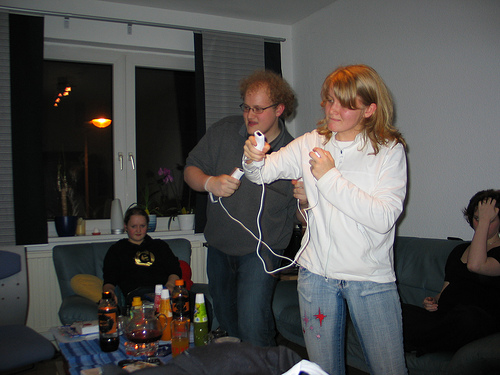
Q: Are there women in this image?
A: Yes, there is a woman.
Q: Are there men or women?
A: Yes, there is a woman.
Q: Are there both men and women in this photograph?
A: Yes, there are both a woman and a man.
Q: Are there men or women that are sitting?
A: Yes, the woman is sitting.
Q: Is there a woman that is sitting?
A: Yes, there is a woman that is sitting.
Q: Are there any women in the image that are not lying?
A: Yes, there is a woman that is sitting.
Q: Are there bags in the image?
A: No, there are no bags.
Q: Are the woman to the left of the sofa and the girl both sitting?
A: Yes, both the woman and the girl are sitting.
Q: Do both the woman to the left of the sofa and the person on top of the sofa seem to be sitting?
A: Yes, both the woman and the girl are sitting.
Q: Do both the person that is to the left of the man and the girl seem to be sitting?
A: Yes, both the woman and the girl are sitting.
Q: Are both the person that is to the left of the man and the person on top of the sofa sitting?
A: Yes, both the woman and the girl are sitting.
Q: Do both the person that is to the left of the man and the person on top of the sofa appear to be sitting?
A: Yes, both the woman and the girl are sitting.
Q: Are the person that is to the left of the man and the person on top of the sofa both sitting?
A: Yes, both the woman and the girl are sitting.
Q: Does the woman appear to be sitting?
A: Yes, the woman is sitting.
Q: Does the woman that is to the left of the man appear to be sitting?
A: Yes, the woman is sitting.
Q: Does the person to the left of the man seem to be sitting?
A: Yes, the woman is sitting.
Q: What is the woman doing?
A: The woman is sitting.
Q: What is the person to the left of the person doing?
A: The woman is sitting.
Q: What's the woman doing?
A: The woman is sitting.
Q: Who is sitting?
A: The woman is sitting.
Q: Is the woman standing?
A: No, the woman is sitting.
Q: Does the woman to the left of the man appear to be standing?
A: No, the woman is sitting.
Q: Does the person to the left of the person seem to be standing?
A: No, the woman is sitting.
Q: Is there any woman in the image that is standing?
A: No, there is a woman but she is sitting.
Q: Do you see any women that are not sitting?
A: No, there is a woman but she is sitting.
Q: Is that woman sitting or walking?
A: The woman is sitting.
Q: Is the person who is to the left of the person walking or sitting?
A: The woman is sitting.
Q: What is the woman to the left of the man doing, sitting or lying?
A: The woman is sitting.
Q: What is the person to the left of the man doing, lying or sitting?
A: The woman is sitting.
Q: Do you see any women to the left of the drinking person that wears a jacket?
A: Yes, there is a woman to the left of the person.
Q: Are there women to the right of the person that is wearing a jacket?
A: No, the woman is to the left of the person.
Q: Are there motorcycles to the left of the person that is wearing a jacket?
A: No, there is a woman to the left of the person.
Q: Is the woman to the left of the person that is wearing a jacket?
A: Yes, the woman is to the left of the person.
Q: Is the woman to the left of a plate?
A: No, the woman is to the left of the person.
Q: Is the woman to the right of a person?
A: No, the woman is to the left of a person.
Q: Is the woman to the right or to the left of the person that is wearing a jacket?
A: The woman is to the left of the person.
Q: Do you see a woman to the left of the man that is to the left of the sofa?
A: Yes, there is a woman to the left of the man.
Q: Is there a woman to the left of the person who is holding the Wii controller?
A: Yes, there is a woman to the left of the man.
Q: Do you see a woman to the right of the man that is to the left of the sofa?
A: No, the woman is to the left of the man.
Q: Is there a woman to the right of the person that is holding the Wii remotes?
A: No, the woman is to the left of the man.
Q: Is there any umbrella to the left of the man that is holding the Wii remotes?
A: No, there is a woman to the left of the man.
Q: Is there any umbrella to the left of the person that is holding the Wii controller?
A: No, there is a woman to the left of the man.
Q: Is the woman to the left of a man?
A: Yes, the woman is to the left of a man.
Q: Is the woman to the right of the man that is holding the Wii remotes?
A: No, the woman is to the left of the man.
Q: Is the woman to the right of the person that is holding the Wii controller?
A: No, the woman is to the left of the man.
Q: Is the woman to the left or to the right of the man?
A: The woman is to the left of the man.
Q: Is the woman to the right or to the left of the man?
A: The woman is to the left of the man.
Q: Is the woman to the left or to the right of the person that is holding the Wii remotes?
A: The woman is to the left of the man.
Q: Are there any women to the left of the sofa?
A: Yes, there is a woman to the left of the sofa.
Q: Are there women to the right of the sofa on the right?
A: No, the woman is to the left of the sofa.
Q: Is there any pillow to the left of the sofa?
A: No, there is a woman to the left of the sofa.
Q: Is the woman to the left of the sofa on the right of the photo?
A: Yes, the woman is to the left of the sofa.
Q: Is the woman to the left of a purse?
A: No, the woman is to the left of the sofa.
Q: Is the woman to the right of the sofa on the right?
A: No, the woman is to the left of the sofa.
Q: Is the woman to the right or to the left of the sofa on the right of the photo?
A: The woman is to the left of the sofa.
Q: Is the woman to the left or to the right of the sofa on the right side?
A: The woman is to the left of the sofa.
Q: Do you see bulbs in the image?
A: No, there are no bulbs.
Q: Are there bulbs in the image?
A: No, there are no bulbs.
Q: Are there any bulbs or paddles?
A: No, there are no bulbs or paddles.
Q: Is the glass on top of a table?
A: Yes, the glass is on top of a table.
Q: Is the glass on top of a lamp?
A: No, the glass is on top of a table.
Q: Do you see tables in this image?
A: Yes, there is a table.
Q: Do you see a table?
A: Yes, there is a table.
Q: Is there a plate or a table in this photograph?
A: Yes, there is a table.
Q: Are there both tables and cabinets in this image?
A: No, there is a table but no cabinets.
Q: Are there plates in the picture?
A: No, there are no plates.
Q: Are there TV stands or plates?
A: No, there are no plates or TV stands.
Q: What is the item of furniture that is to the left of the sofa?
A: The piece of furniture is a table.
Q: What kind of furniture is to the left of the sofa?
A: The piece of furniture is a table.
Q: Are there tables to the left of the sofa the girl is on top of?
A: Yes, there is a table to the left of the sofa.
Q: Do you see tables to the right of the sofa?
A: No, the table is to the left of the sofa.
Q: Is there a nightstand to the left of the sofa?
A: No, there is a table to the left of the sofa.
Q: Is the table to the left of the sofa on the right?
A: Yes, the table is to the left of the sofa.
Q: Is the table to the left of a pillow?
A: No, the table is to the left of the sofa.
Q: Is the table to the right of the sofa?
A: No, the table is to the left of the sofa.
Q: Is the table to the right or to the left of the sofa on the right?
A: The table is to the left of the sofa.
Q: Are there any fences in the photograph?
A: No, there are no fences.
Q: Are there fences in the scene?
A: No, there are no fences.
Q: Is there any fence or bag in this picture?
A: No, there are no fences or bags.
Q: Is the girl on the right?
A: Yes, the girl is on the right of the image.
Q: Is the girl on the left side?
A: No, the girl is on the right of the image.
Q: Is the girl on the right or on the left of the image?
A: The girl is on the right of the image.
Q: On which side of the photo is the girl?
A: The girl is on the right of the image.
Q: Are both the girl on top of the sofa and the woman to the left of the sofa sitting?
A: Yes, both the girl and the woman are sitting.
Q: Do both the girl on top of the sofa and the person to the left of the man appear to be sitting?
A: Yes, both the girl and the woman are sitting.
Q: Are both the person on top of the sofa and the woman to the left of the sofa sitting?
A: Yes, both the girl and the woman are sitting.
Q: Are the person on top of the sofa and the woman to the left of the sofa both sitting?
A: Yes, both the girl and the woman are sitting.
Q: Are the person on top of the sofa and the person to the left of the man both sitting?
A: Yes, both the girl and the woman are sitting.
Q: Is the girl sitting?
A: Yes, the girl is sitting.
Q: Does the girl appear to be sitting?
A: Yes, the girl is sitting.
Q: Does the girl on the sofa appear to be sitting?
A: Yes, the girl is sitting.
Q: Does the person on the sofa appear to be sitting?
A: Yes, the girl is sitting.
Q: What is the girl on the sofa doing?
A: The girl is sitting.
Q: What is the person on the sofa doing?
A: The girl is sitting.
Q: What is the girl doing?
A: The girl is sitting.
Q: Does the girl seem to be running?
A: No, the girl is sitting.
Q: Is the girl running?
A: No, the girl is sitting.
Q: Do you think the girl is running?
A: No, the girl is sitting.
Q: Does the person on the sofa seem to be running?
A: No, the girl is sitting.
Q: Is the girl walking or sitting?
A: The girl is sitting.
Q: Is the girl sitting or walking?
A: The girl is sitting.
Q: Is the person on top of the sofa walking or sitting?
A: The girl is sitting.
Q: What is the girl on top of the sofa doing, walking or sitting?
A: The girl is sitting.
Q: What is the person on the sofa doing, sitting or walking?
A: The girl is sitting.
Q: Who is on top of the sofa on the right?
A: The girl is on top of the sofa.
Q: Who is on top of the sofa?
A: The girl is on top of the sofa.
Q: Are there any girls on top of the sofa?
A: Yes, there is a girl on top of the sofa.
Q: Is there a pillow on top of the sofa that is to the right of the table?
A: No, there is a girl on top of the sofa.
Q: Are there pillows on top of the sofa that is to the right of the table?
A: No, there is a girl on top of the sofa.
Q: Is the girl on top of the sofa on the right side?
A: Yes, the girl is on top of the sofa.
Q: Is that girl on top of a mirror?
A: No, the girl is on top of the sofa.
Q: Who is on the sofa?
A: The girl is on the sofa.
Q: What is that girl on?
A: The girl is on the sofa.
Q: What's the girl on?
A: The girl is on the sofa.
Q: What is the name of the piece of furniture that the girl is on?
A: The piece of furniture is a sofa.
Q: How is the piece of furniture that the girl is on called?
A: The piece of furniture is a sofa.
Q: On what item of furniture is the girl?
A: The girl is on the sofa.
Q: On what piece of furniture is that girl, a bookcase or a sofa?
A: The girl is on a sofa.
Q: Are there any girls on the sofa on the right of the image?
A: Yes, there is a girl on the sofa.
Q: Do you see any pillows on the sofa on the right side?
A: No, there is a girl on the sofa.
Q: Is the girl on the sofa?
A: Yes, the girl is on the sofa.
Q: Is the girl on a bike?
A: No, the girl is on the sofa.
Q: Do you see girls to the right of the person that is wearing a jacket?
A: Yes, there is a girl to the right of the person.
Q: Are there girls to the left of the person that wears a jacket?
A: No, the girl is to the right of the person.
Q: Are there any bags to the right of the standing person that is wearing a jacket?
A: No, there is a girl to the right of the person.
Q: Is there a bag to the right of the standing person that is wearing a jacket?
A: No, there is a girl to the right of the person.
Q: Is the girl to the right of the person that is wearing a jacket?
A: Yes, the girl is to the right of the person.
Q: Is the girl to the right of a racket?
A: No, the girl is to the right of the person.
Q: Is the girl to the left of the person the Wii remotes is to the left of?
A: No, the girl is to the right of the person.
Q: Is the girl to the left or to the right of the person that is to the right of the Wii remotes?
A: The girl is to the right of the person.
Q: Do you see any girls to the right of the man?
A: Yes, there is a girl to the right of the man.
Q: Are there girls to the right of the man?
A: Yes, there is a girl to the right of the man.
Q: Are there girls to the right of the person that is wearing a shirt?
A: Yes, there is a girl to the right of the man.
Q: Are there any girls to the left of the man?
A: No, the girl is to the right of the man.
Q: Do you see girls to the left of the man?
A: No, the girl is to the right of the man.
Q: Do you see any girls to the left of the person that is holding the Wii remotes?
A: No, the girl is to the right of the man.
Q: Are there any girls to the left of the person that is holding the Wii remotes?
A: No, the girl is to the right of the man.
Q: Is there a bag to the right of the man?
A: No, there is a girl to the right of the man.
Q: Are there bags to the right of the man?
A: No, there is a girl to the right of the man.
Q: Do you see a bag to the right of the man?
A: No, there is a girl to the right of the man.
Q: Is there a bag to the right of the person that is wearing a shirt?
A: No, there is a girl to the right of the man.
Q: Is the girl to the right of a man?
A: Yes, the girl is to the right of a man.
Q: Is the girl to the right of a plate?
A: No, the girl is to the right of a man.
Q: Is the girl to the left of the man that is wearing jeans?
A: No, the girl is to the right of the man.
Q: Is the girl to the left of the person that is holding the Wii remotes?
A: No, the girl is to the right of the man.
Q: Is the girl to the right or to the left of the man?
A: The girl is to the right of the man.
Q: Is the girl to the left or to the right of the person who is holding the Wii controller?
A: The girl is to the right of the man.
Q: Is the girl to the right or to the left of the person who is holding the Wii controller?
A: The girl is to the right of the man.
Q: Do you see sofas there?
A: Yes, there is a sofa.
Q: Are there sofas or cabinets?
A: Yes, there is a sofa.